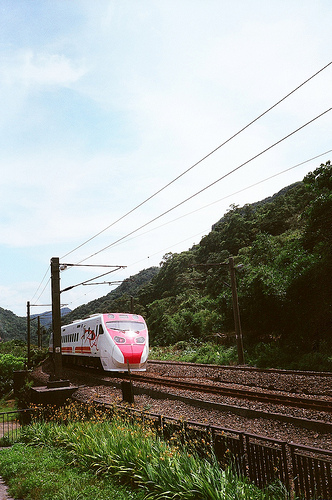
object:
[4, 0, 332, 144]
sky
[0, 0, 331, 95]
clouds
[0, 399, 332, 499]
fence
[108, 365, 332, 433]
rail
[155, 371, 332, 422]
rail train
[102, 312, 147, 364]
red lights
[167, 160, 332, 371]
hill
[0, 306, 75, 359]
hill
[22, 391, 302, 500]
plants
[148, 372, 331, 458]
gravel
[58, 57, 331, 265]
electrical wire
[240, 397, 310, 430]
track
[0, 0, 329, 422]
daytime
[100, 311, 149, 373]
front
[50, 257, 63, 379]
pole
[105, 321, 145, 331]
window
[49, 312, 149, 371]
rail train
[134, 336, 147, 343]
lights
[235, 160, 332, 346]
tree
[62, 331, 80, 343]
passenger window